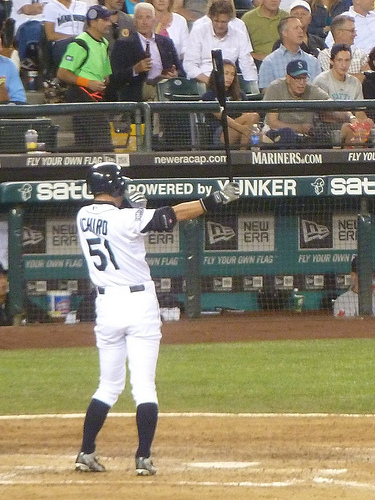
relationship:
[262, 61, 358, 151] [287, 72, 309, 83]
man has glasses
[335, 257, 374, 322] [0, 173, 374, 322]
person inside dugout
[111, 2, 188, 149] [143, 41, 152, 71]
man has beer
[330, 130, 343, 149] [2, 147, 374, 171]
cup on top of ledge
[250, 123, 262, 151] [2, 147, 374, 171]
bottle on top of ledge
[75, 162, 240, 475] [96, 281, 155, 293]
player has belt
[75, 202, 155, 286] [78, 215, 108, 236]
shirt has name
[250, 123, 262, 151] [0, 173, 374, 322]
bottle above dugout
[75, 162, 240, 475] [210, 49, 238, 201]
player holding bat